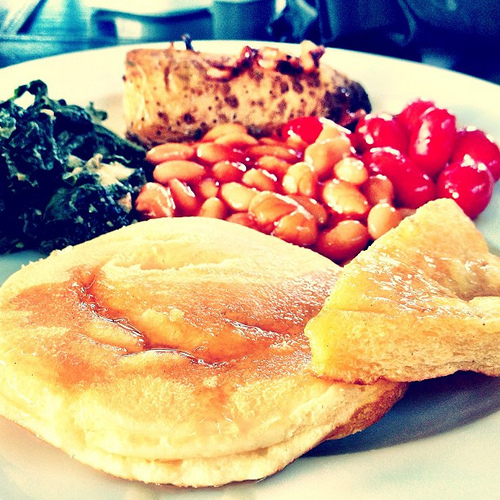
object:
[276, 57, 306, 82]
burn marks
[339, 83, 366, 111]
burn marks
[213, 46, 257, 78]
burn marks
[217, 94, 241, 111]
burn marks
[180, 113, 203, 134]
burn marks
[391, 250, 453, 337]
biscuit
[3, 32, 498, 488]
food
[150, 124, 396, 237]
bean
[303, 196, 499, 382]
bread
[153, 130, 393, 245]
brown bean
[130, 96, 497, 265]
sauce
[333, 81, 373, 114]
burnt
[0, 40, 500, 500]
plate